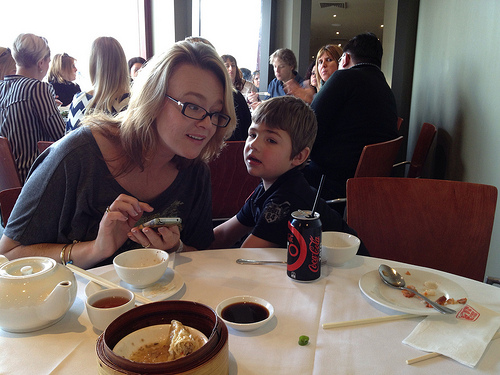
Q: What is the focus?
A: Child whispering in adult ear.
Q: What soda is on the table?
A: Coke zero.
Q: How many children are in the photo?
A: 1.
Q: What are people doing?
A: Eating.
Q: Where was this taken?
A: Restaurant.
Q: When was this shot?
A: Daytime.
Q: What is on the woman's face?
A: Glasses.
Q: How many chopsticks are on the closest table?
A: 4.